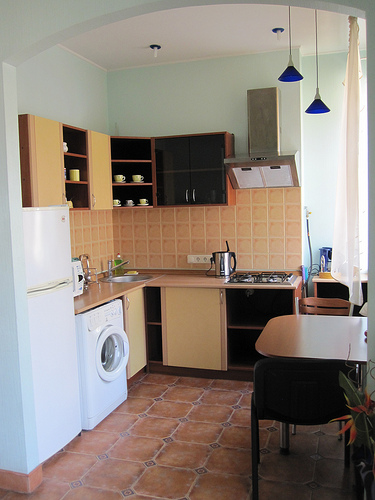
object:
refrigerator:
[20, 205, 82, 474]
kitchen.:
[0, 0, 373, 499]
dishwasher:
[75, 298, 131, 430]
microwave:
[69, 258, 84, 298]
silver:
[215, 251, 233, 279]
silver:
[225, 272, 293, 286]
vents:
[223, 86, 301, 191]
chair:
[251, 356, 361, 499]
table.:
[254, 313, 369, 364]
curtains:
[330, 15, 366, 307]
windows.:
[331, 14, 365, 306]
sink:
[99, 260, 150, 283]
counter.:
[73, 266, 301, 315]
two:
[19, 203, 83, 465]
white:
[74, 298, 129, 431]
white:
[72, 262, 86, 296]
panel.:
[72, 261, 85, 298]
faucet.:
[107, 259, 130, 277]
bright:
[114, 252, 124, 276]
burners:
[226, 270, 298, 286]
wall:
[0, 41, 375, 299]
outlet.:
[187, 255, 215, 263]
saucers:
[113, 174, 150, 206]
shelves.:
[62, 123, 154, 211]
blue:
[277, 3, 330, 114]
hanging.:
[277, 5, 331, 116]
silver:
[223, 87, 301, 190]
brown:
[110, 159, 150, 163]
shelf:
[92, 194, 96, 208]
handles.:
[89, 191, 98, 209]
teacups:
[114, 174, 145, 183]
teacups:
[112, 199, 149, 207]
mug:
[69, 169, 80, 181]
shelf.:
[64, 179, 88, 184]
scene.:
[0, 0, 374, 498]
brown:
[1, 368, 374, 499]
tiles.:
[2, 369, 375, 500]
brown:
[17, 114, 304, 381]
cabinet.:
[18, 113, 303, 380]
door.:
[95, 324, 130, 383]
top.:
[254, 313, 368, 366]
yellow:
[114, 174, 145, 183]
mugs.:
[113, 175, 126, 184]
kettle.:
[205, 240, 237, 277]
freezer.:
[23, 205, 74, 297]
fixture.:
[278, 6, 332, 114]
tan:
[69, 185, 302, 273]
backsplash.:
[69, 204, 302, 271]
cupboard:
[155, 135, 226, 209]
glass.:
[153, 133, 230, 206]